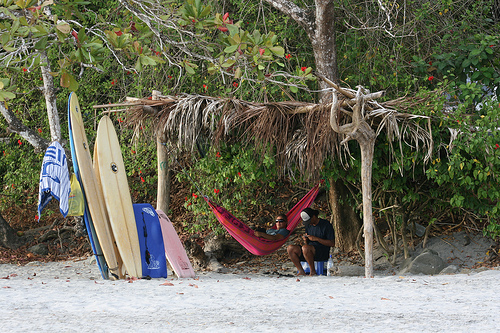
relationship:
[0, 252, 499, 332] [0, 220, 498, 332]
sand on top of ground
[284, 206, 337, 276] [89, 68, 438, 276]
person sitting under shack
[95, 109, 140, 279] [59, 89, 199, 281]
surfboard part of group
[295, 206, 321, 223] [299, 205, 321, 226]
hat on top of head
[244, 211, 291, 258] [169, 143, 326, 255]
man lying in hammock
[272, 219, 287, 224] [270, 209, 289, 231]
sunglasses worn on face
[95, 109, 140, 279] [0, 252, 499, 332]
surfboard stuck in sand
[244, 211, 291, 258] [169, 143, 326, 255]
man laying in hammock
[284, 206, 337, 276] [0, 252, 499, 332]
person sitting on sand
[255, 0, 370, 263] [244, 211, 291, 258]
tree behind man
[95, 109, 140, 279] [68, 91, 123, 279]
surfboard lined up with another surfboard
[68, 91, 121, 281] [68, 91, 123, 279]
another surfboard lined up with another surfboard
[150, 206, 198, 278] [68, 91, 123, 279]
boogie board lined up with another surfboard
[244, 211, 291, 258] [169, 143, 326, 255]
man laying in a hammock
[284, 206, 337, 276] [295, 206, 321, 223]
person wearing a hat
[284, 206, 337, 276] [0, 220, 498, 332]
person sitting on ground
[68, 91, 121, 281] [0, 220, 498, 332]
another surfboard on top of ground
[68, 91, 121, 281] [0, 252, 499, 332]
another surfboard on top of sand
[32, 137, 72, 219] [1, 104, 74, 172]
towel hanging on a branch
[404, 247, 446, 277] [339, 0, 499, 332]
stone sitting to right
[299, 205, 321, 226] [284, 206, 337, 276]
head of a person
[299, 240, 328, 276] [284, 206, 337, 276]
leg of a person